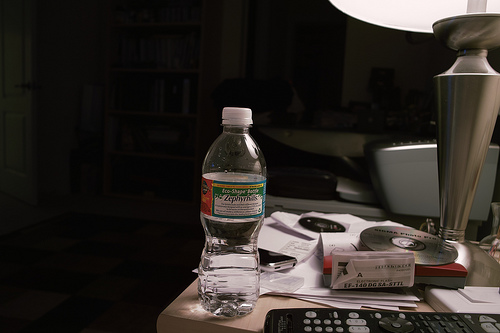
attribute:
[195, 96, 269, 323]
bottle — plastic, half-empty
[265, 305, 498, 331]
remote — black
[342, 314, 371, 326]
button — white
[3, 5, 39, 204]
door — white, open, wooden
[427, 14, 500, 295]
base — metal, silver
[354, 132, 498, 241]
printer — gray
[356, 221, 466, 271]
compact disc — silver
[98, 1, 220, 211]
shelves — wooden, tall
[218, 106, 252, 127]
cap — white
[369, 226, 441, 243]
writing — black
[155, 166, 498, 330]
desk — messy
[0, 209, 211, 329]
rug — checkered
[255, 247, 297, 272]
cellphone — black, silver